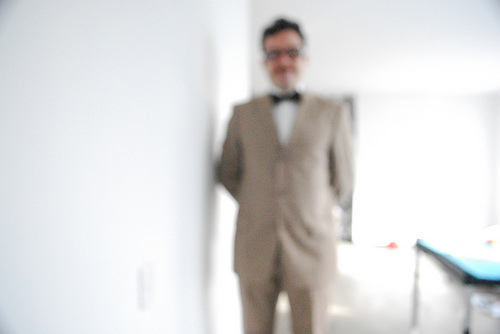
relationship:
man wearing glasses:
[213, 19, 358, 334] [253, 38, 333, 68]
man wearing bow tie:
[213, 19, 358, 334] [261, 83, 313, 109]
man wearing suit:
[209, 19, 358, 331] [217, 95, 357, 329]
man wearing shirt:
[213, 19, 358, 334] [209, 81, 396, 190]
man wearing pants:
[209, 19, 358, 331] [229, 283, 328, 330]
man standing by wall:
[213, 19, 358, 334] [1, 2, 250, 332]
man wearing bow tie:
[209, 19, 358, 331] [263, 85, 305, 109]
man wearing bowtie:
[213, 19, 358, 334] [267, 91, 300, 105]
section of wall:
[0, 0, 499, 334] [1, 2, 250, 332]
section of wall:
[110, 238, 195, 285] [49, 78, 185, 203]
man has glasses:
[213, 19, 358, 334] [250, 20, 357, 75]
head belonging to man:
[235, 7, 325, 102] [209, 19, 358, 331]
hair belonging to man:
[261, 19, 303, 49] [209, 19, 358, 331]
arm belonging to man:
[325, 105, 356, 212] [209, 19, 358, 331]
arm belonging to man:
[215, 100, 242, 200] [209, 19, 358, 331]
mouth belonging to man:
[271, 64, 301, 81] [199, 22, 371, 332]